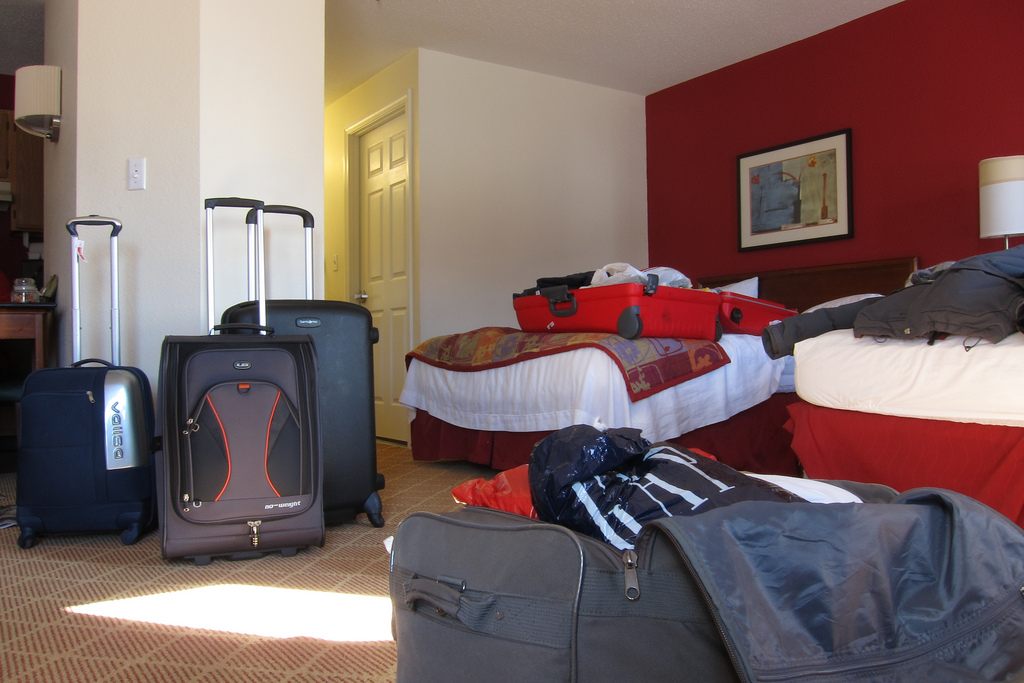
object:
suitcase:
[14, 214, 164, 550]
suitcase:
[154, 196, 326, 566]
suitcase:
[219, 205, 388, 529]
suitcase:
[512, 275, 799, 343]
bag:
[389, 423, 1022, 681]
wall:
[646, 0, 1023, 288]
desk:
[0, 304, 60, 437]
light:
[60, 582, 399, 644]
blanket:
[405, 327, 733, 403]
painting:
[736, 128, 853, 253]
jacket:
[761, 243, 1024, 361]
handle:
[65, 213, 123, 366]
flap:
[638, 487, 1022, 683]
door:
[347, 94, 412, 446]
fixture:
[13, 65, 63, 142]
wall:
[43, 0, 76, 369]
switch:
[128, 158, 145, 190]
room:
[0, 0, 1022, 682]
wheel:
[120, 522, 142, 545]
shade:
[980, 156, 1023, 240]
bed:
[410, 329, 796, 476]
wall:
[72, 0, 327, 397]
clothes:
[451, 423, 864, 551]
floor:
[0, 438, 499, 681]